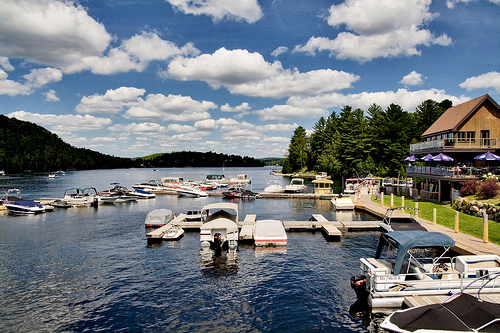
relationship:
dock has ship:
[158, 202, 267, 271] [141, 208, 178, 228]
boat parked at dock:
[201, 202, 241, 250] [252, 185, 339, 202]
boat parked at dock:
[280, 174, 308, 194] [252, 185, 339, 202]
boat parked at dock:
[351, 229, 498, 324] [287, 212, 412, 239]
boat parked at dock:
[5, 191, 60, 216] [287, 212, 412, 239]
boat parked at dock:
[137, 171, 194, 202] [287, 212, 412, 239]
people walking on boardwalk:
[350, 172, 389, 205] [372, 185, 472, 256]